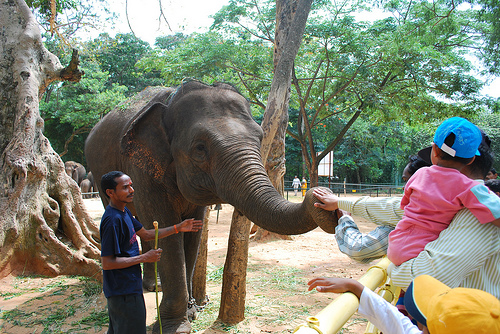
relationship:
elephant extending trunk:
[82, 78, 340, 333] [208, 132, 341, 236]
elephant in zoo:
[72, 70, 344, 332] [2, 3, 426, 332]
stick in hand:
[149, 219, 166, 332] [144, 245, 163, 261]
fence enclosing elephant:
[71, 176, 405, 208] [72, 70, 344, 332]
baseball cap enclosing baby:
[418, 105, 497, 171] [378, 110, 484, 274]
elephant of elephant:
[82, 78, 340, 333] [72, 70, 344, 332]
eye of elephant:
[192, 142, 207, 154] [72, 70, 344, 332]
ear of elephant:
[117, 96, 174, 192] [72, 70, 344, 332]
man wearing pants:
[92, 174, 200, 329] [100, 287, 151, 331]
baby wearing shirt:
[386, 117, 498, 265] [389, 170, 492, 253]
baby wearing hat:
[386, 117, 498, 265] [425, 110, 486, 159]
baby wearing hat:
[386, 117, 498, 265] [404, 267, 499, 330]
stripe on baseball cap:
[400, 280, 425, 329] [432, 117, 481, 158]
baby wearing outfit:
[386, 117, 498, 265] [408, 170, 455, 250]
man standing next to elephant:
[98, 169, 202, 334] [88, 76, 356, 279]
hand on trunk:
[144, 248, 163, 263] [217, 137, 345, 235]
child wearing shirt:
[306, 273, 499, 331] [352, 284, 421, 332]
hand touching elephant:
[314, 184, 336, 214] [72, 70, 344, 332]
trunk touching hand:
[220, 151, 334, 245] [310, 186, 337, 212]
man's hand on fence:
[307, 276, 362, 294] [296, 256, 392, 331]